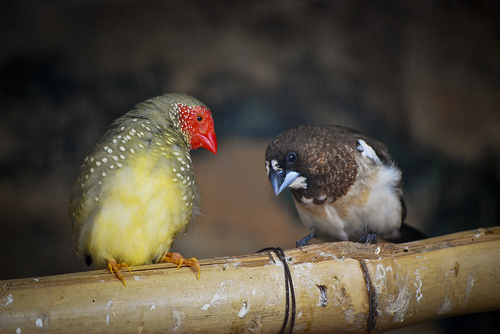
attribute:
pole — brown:
[0, 226, 498, 331]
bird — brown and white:
[264, 122, 415, 247]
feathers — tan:
[322, 184, 400, 236]